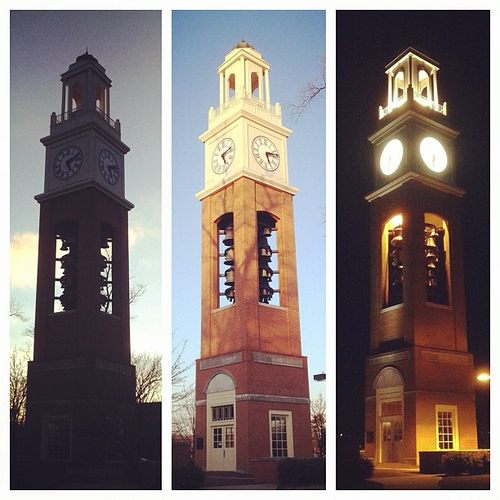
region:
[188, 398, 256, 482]
the door is white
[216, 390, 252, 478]
the door is white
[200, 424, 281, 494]
the door is white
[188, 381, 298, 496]
the door is white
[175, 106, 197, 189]
this is the sky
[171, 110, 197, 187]
the sky is blue in color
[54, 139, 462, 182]
these are three clocks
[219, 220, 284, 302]
these are several bells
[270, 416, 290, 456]
this is a window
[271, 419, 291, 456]
the window is closed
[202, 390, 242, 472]
this is a door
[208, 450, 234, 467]
the door is white in color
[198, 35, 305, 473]
the building is tall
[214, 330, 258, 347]
the wall is brown in color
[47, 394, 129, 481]
the door is dark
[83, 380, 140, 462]
the door is dark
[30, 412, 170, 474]
the door is dark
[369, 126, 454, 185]
Illuminated clock faces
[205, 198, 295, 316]
Tower bells in the daylight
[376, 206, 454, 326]
Tower bells at night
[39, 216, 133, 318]
Tower bells at dusk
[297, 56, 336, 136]
A tree limb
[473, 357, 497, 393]
Light seperate from the tower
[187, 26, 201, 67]
Blue sky during daytime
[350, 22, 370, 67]
Dark sky at night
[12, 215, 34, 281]
A cloud at dusk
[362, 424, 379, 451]
A plaque on the tower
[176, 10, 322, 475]
image of a clock tower during the day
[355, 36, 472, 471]
image of a clock tower at night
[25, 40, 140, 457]
image of clock tower at dawn or dusk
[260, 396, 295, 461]
windows on side of tower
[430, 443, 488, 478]
well-manicured shrubbery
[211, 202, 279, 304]
bells inside tower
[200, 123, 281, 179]
clocks on sides of tower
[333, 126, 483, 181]
illuminated clock faces at night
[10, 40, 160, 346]
clouds in sky behind tower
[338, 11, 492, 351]
area around tower is completely dark